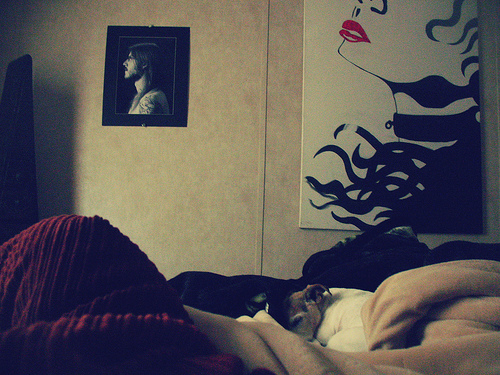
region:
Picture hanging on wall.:
[106, 33, 184, 125]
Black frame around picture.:
[101, 70, 202, 147]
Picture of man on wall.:
[118, 45, 189, 129]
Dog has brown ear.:
[305, 280, 330, 307]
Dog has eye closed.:
[293, 307, 303, 334]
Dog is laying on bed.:
[231, 267, 345, 334]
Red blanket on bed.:
[71, 256, 143, 342]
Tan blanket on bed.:
[222, 326, 311, 362]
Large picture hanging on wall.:
[274, 38, 453, 188]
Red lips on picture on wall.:
[337, 16, 377, 49]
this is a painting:
[394, 85, 450, 169]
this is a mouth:
[324, 8, 386, 48]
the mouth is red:
[327, 16, 408, 126]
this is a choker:
[315, 32, 469, 165]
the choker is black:
[412, 46, 438, 207]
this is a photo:
[88, 70, 215, 181]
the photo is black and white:
[110, 42, 141, 94]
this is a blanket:
[67, 179, 163, 341]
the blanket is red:
[119, 308, 151, 355]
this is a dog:
[274, 297, 363, 347]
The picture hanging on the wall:
[93, 17, 207, 133]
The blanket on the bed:
[31, 237, 145, 360]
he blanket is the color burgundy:
[34, 241, 135, 371]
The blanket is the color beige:
[411, 286, 496, 371]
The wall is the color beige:
[74, 137, 261, 198]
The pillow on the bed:
[329, 283, 375, 347]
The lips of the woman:
[334, 16, 373, 49]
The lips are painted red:
[330, 16, 375, 47]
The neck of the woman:
[381, 81, 483, 144]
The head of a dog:
[286, 278, 333, 345]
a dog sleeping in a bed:
[235, 261, 377, 352]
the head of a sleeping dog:
[241, 282, 335, 333]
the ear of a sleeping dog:
[284, 281, 331, 308]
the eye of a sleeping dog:
[275, 308, 299, 318]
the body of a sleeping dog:
[334, 286, 371, 353]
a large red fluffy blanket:
[17, 208, 189, 366]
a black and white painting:
[287, 2, 462, 230]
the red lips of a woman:
[332, 18, 377, 49]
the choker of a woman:
[375, 111, 476, 156]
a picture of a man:
[85, 19, 196, 134]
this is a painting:
[347, 79, 457, 224]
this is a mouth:
[328, 13, 386, 95]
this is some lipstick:
[332, 21, 397, 75]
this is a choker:
[386, 107, 453, 132]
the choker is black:
[382, 85, 437, 167]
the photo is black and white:
[87, 34, 171, 116]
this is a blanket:
[124, 284, 202, 359]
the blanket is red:
[126, 324, 136, 342]